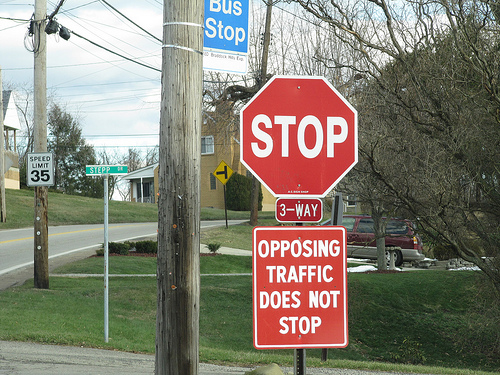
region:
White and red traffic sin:
[230, 69, 359, 196]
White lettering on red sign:
[257, 236, 269, 260]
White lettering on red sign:
[267, 239, 279, 261]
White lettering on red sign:
[277, 239, 290, 256]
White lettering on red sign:
[291, 238, 313, 265]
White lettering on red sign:
[312, 238, 342, 253]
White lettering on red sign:
[270, 264, 285, 284]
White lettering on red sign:
[287, 264, 306, 286]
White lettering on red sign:
[304, 258, 336, 285]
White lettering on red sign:
[257, 288, 335, 315]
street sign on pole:
[77, 154, 129, 191]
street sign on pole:
[27, 151, 62, 193]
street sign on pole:
[237, 69, 387, 199]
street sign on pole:
[268, 187, 325, 224]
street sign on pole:
[253, 230, 345, 357]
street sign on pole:
[212, 155, 234, 203]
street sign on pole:
[217, 0, 246, 89]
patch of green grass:
[372, 307, 392, 328]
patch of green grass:
[389, 325, 413, 348]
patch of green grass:
[118, 303, 133, 321]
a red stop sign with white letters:
[238, 75, 358, 197]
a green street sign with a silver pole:
[82, 164, 128, 343]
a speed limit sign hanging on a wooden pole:
[24, 150, 55, 187]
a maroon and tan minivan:
[309, 213, 423, 265]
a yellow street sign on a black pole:
[210, 160, 238, 226]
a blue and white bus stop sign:
[202, 1, 250, 74]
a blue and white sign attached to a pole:
[152, 2, 248, 374]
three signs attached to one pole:
[238, 73, 358, 373]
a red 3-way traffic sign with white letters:
[274, 195, 326, 222]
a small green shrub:
[206, 241, 222, 256]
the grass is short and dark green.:
[369, 276, 413, 333]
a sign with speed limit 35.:
[25, 150, 55, 191]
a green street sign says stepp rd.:
[84, 161, 128, 178]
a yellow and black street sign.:
[211, 160, 232, 180]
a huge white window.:
[199, 135, 214, 155]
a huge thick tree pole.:
[156, 0, 204, 374]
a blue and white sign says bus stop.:
[200, 0, 252, 76]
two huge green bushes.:
[222, 170, 263, 212]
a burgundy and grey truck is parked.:
[341, 213, 421, 269]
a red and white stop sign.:
[238, 73, 360, 195]